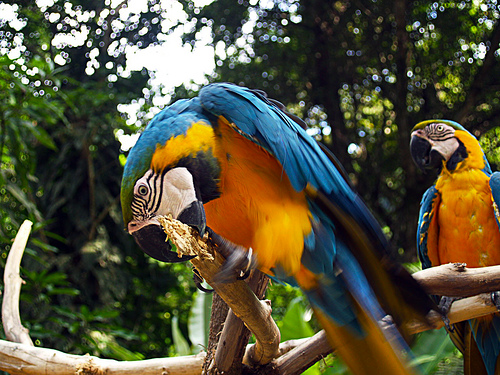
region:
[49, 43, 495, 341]
parrots standing outside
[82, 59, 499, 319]
parrots on an outside branch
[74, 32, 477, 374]
two parrots standng on a branch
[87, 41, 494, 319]
two parrots standing on a tree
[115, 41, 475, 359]
two parrots standign on a tree branch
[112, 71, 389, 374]
a parrot biting the branch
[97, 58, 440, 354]
a parrot with his head down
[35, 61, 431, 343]
a parrot with green white and yellow colors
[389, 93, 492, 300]
a parrot that is standing up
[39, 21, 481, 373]
a tree with parrots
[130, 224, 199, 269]
The birds beak is black.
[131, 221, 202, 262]
The birds beak is large.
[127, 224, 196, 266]
The birds beak has a point.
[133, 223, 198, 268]
The birds beak is sharp.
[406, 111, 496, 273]
The bird is sitting on the branch.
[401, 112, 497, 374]
The bird is has many colors.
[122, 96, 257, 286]
The bird is eating the branch.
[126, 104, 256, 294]
The bird is holding the branch.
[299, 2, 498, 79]
The trees in the background are green.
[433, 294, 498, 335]
The birds claws are black.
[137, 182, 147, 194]
the black and white eye of the parrot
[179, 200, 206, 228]
the black bottom beak of the parrot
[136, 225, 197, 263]
the black upper beak of the parrot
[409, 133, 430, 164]
the black beak of the parrot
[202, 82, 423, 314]
the blue wing of the parrot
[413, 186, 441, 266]
the blue wing of the parrot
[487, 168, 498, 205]
the blue wing of the parrot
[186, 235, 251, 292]
the black claw of the parrot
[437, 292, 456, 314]
the black claw of the parrot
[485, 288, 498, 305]
the black claw of the parrot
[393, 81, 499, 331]
Colorful bird on a branch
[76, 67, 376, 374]
Colorful bird on a branch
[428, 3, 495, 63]
Green leaves on a tree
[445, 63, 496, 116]
Green leaves on a tree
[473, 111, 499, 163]
Green leaves on a tree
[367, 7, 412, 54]
Green leaves on a tree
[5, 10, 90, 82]
Green leaves on a tree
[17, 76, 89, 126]
Green leaves on a tree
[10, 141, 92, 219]
Green leaves on a tree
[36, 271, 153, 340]
Green leaves on a tree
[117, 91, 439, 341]
a colorful parrot on tree branch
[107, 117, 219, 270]
head of a parrot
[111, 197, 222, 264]
beck of a parrot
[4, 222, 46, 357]
a sturdy tree branch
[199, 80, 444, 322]
wings of a parrot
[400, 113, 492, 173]
head of a parrot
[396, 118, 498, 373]
a parrot hanging on tree branch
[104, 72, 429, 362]
parrot pecking out a tree branch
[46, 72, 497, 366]
two parrot holding on tree branch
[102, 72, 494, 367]
two colorful parrot hanging on